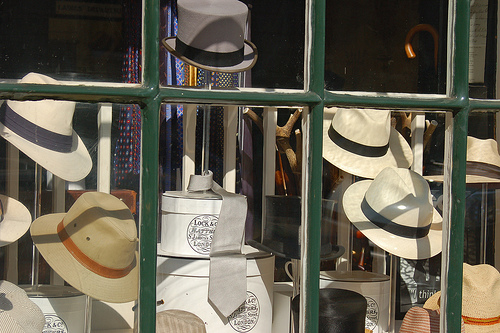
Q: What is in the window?
A: Hats.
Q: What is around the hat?
A: Ribbon.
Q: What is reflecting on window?
A: Light.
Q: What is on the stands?
A: Hat.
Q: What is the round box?
A: Hat box.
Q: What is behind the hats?
A: Ties.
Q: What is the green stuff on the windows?
A: Pains.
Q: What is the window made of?
A: Glass.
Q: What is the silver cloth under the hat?
A: Tie.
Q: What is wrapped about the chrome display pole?
A: A tie.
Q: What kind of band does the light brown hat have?
A: A chocolate covered band.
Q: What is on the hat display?
A: Hats.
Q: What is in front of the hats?
A: A green-framed glass window.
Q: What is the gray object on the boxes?
A: A tie.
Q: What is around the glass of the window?
A: Green rim.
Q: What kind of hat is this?
A: A top hat.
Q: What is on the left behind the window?
A: Hats.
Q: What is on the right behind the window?
A: Hats.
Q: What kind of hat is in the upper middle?
A: A top hat.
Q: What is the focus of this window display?
A: Hats.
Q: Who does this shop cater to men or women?
A: Men.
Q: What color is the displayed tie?
A: Grey.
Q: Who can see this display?
A: People passing by outside.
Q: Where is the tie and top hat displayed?
A: On hat boxes.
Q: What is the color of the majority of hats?
A: White.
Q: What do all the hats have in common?
A: They all have a colored band.